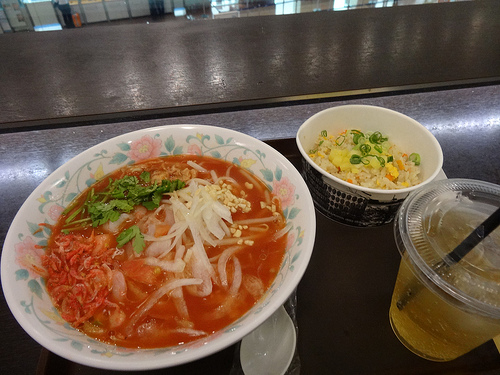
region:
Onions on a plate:
[178, 203, 221, 233]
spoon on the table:
[248, 330, 300, 374]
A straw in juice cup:
[455, 229, 494, 246]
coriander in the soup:
[93, 183, 148, 205]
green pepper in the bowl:
[353, 141, 378, 155]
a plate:
[3, 302, 46, 329]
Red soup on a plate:
[185, 300, 206, 320]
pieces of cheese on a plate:
[220, 187, 240, 204]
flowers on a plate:
[40, 187, 70, 204]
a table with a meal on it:
[8, 148, 53, 172]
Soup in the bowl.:
[74, 189, 242, 321]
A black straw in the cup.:
[445, 200, 499, 248]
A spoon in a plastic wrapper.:
[229, 330, 316, 372]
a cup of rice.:
[304, 90, 419, 198]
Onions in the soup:
[156, 209, 238, 269]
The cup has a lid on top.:
[415, 183, 493, 307]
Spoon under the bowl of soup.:
[222, 317, 317, 368]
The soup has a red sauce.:
[86, 223, 229, 318]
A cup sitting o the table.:
[398, 165, 483, 341]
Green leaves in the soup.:
[95, 174, 177, 216]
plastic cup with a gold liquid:
[387, 194, 498, 345]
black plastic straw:
[393, 206, 498, 311]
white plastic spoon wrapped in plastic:
[230, 293, 313, 373]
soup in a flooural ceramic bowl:
[20, 118, 305, 346]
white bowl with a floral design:
[29, 112, 291, 357]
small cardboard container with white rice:
[312, 100, 440, 216]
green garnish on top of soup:
[70, 159, 186, 244]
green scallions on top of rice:
[330, 128, 393, 162]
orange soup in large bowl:
[30, 113, 297, 358]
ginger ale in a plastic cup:
[396, 165, 497, 346]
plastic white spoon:
[232, 285, 297, 372]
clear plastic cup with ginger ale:
[388, 171, 498, 345]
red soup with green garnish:
[13, 121, 298, 360]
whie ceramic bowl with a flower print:
[18, 128, 303, 365]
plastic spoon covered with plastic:
[231, 290, 315, 372]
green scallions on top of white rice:
[340, 125, 416, 160]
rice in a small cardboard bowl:
[300, 95, 446, 217]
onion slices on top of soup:
[161, 181, 231, 298]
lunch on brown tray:
[32, 128, 486, 370]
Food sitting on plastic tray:
[5, 95, 499, 372]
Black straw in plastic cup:
[393, 205, 499, 317]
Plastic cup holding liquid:
[386, 174, 498, 366]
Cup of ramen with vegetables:
[295, 103, 448, 230]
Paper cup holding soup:
[291, 103, 445, 230]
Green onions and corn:
[331, 126, 403, 172]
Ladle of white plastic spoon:
[235, 307, 302, 373]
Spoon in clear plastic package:
[224, 294, 306, 374]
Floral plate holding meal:
[7, 116, 324, 369]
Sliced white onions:
[163, 186, 238, 263]